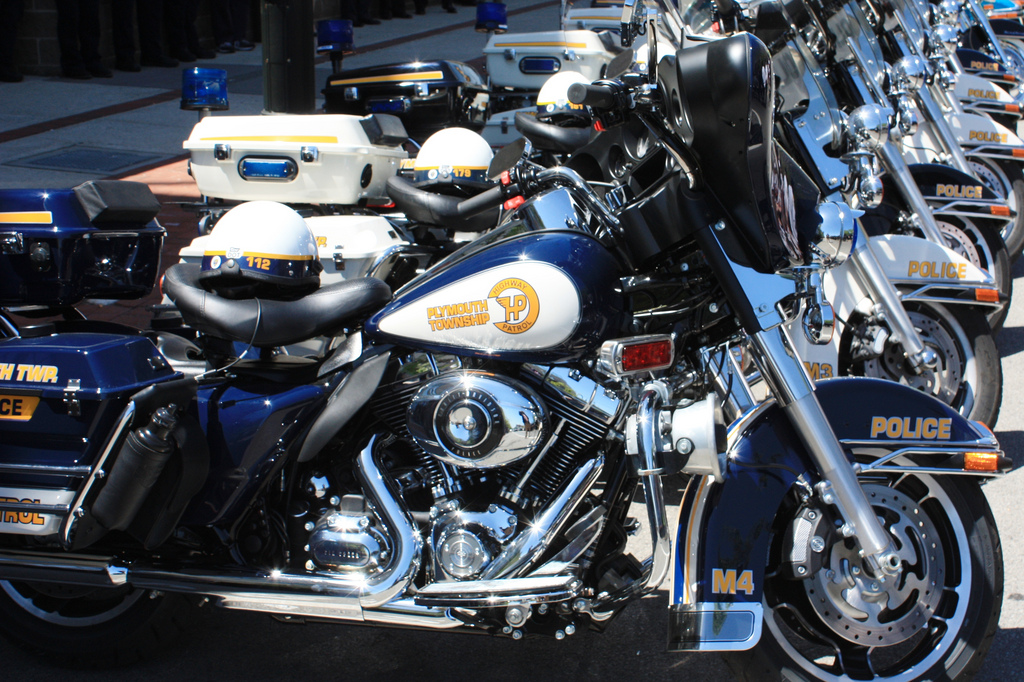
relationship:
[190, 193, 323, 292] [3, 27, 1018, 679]
helmet on motorcycle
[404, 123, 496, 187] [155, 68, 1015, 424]
helmet on motorcycle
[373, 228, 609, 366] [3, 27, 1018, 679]
gas tank on motorcycle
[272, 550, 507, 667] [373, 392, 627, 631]
chrome on motor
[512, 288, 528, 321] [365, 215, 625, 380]
letter on gas tank